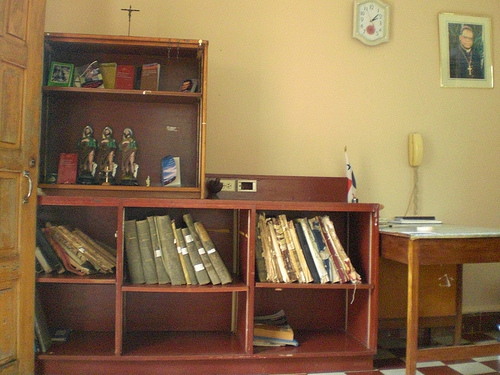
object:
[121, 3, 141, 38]
cross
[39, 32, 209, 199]
shelf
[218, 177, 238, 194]
outlet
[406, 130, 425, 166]
phone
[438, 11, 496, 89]
picture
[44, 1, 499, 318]
wall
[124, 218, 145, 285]
book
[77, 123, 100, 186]
religious statue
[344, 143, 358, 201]
flag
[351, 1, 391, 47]
clock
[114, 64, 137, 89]
book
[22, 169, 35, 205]
handle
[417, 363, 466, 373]
floor tile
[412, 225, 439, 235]
white top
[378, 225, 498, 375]
wooden desk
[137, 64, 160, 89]
book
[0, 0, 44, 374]
door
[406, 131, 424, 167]
telephone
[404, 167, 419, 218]
cord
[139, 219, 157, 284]
book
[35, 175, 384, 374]
shelf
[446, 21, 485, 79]
photo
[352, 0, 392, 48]
white frame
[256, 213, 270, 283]
book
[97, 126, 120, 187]
statue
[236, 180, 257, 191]
outlet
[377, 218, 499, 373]
desk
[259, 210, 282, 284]
binding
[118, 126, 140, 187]
figure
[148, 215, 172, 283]
book